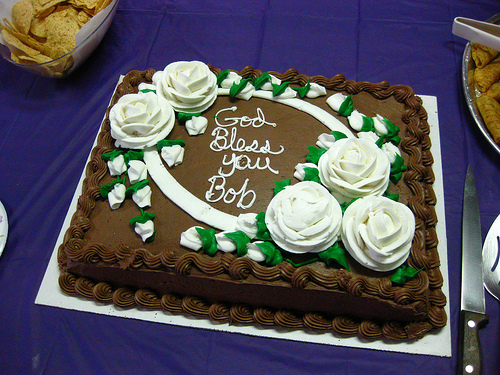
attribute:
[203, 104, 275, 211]
letters — white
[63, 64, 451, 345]
cake — rectangular, brown, chocolate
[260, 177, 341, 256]
rose — white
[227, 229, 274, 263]
leaves — green 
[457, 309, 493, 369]
handle — black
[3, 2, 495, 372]
cloth — blue, purple , paper, table, royal blue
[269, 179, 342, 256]
rose — white , large 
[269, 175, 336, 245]
rose — white 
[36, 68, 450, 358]
cardboard — white 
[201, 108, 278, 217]
message — white 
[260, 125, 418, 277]
flowers — white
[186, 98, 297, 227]
writing — god bless you bob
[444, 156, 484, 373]
knife — pointy metal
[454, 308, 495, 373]
handle — wooden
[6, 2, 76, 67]
chips — tortilla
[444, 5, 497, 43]
tongs — pair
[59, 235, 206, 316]
icing — chocolate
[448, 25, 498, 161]
tin — circular, metal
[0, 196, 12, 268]
plate — paper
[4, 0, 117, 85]
dish — glass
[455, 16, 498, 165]
platter — silver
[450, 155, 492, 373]
knife — long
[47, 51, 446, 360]
cake — chocolate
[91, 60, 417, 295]
icing — brown, green, white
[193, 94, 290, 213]
writing — white, icing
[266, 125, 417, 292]
petals — three, white, flower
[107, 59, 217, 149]
petals — flower, white, icing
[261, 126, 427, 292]
flowers — white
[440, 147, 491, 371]
knife — black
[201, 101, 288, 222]
writing — god bless you bob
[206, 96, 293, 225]
writing — god bless you bob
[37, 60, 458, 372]
cake — chocolate, frosted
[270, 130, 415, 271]
flowers — white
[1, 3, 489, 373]
table — blue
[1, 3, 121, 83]
bowl — chips